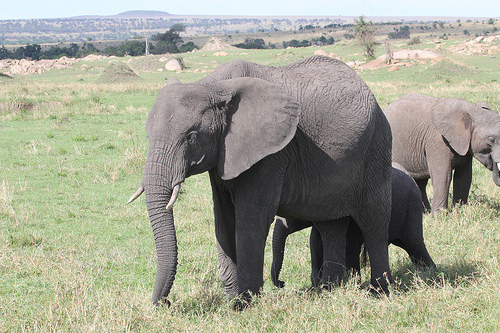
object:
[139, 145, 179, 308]
trunk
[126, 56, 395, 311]
elephant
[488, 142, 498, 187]
trunk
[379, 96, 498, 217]
elephant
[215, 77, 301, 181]
left ear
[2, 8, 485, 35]
mountain range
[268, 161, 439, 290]
elephant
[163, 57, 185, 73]
boulder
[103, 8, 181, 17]
hill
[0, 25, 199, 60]
trees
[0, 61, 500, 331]
grass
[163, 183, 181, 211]
tusk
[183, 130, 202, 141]
left eye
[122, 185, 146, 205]
tusk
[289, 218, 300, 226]
right eye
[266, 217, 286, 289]
trunk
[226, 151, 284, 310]
left leg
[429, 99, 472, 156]
right ear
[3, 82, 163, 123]
grass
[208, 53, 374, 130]
back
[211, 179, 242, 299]
front leg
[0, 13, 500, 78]
terrain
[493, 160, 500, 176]
tusk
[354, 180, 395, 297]
back leg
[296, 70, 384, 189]
body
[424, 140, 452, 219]
leg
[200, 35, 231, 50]
mound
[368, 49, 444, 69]
mound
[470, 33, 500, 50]
mound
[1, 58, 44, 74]
mound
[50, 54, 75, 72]
mound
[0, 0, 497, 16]
sky